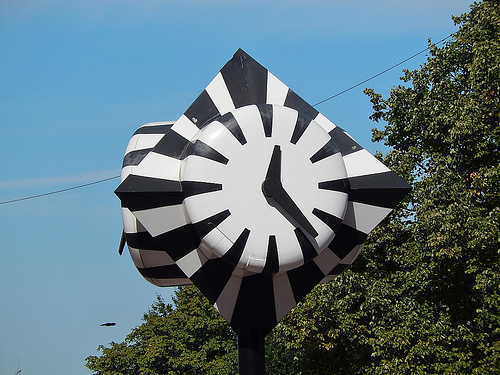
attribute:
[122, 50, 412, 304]
stripes — zebra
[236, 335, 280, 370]
pole — black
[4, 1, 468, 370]
sky — clear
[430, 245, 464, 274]
branch — tree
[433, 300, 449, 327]
branch — tree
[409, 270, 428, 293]
branch — tree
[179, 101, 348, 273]
clock — black, white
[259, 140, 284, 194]
arm — black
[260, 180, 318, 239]
arm — black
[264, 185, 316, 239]
arm — black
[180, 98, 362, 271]
clock — modern, modern-looking, tall, black, white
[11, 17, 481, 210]
power lines — high-voltage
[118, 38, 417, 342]
outside clock — tall